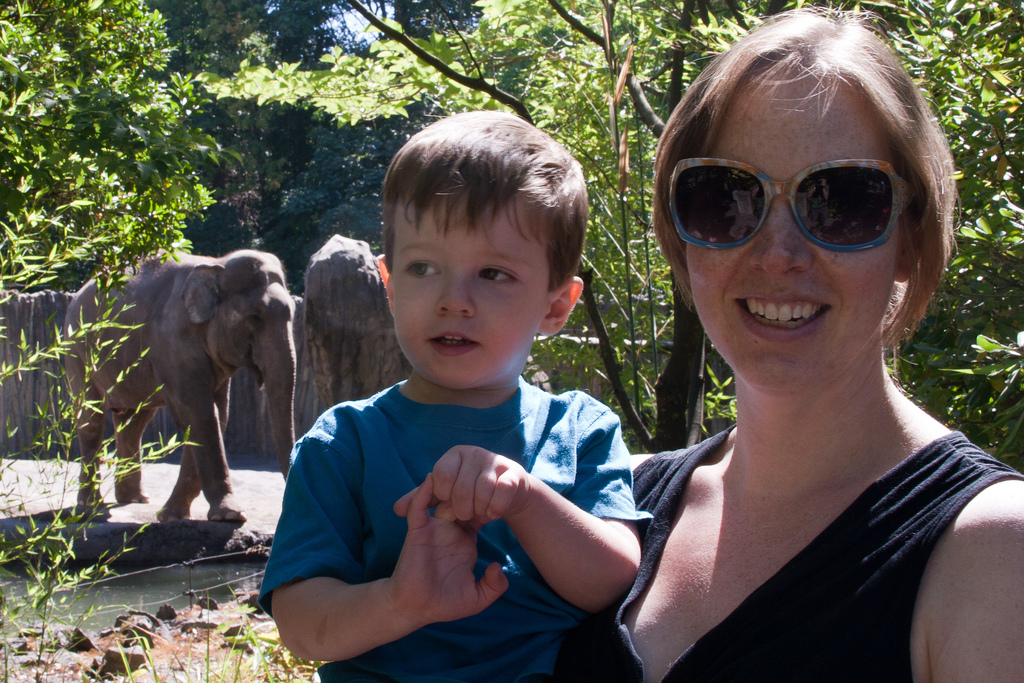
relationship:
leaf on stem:
[204, 616, 225, 636] [200, 600, 216, 680]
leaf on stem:
[229, 594, 248, 608] [234, 594, 244, 680]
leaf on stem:
[67, 540, 81, 557] [0, 534, 81, 589]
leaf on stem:
[61, 531, 75, 548] [0, 512, 77, 554]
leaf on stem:
[23, 506, 43, 522] [19, 506, 43, 620]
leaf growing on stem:
[179, 433, 196, 449] [80, 423, 199, 487]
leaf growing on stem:
[29, 566, 40, 589] [0, 571, 48, 614]